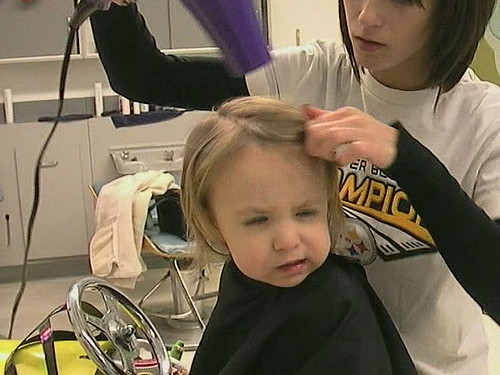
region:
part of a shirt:
[413, 218, 421, 233]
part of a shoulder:
[325, 318, 337, 320]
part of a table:
[138, 251, 145, 269]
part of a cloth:
[329, 335, 345, 342]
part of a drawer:
[73, 198, 81, 211]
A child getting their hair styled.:
[78, 3, 488, 373]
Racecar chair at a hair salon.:
[5, 272, 197, 372]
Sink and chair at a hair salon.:
[87, 138, 188, 274]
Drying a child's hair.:
[162, 4, 344, 294]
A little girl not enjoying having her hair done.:
[154, 14, 387, 294]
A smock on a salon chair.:
[88, 162, 197, 283]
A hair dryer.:
[41, 0, 268, 130]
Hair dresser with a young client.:
[143, 1, 454, 295]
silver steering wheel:
[64, 273, 171, 373]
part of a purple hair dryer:
[182, 0, 272, 76]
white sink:
[110, 142, 182, 173]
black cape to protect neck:
[187, 259, 419, 373]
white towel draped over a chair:
[90, 169, 178, 288]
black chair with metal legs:
[88, 177, 217, 327]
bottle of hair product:
[3, 87, 13, 124]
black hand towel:
[99, 108, 195, 128]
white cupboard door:
[14, 144, 86, 259]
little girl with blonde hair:
[179, 95, 420, 374]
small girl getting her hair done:
[177, 85, 347, 295]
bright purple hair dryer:
[55, 0, 277, 82]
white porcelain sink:
[106, 141, 190, 174]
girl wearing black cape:
[180, 91, 420, 373]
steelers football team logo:
[337, 218, 377, 263]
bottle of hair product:
[92, 77, 107, 118]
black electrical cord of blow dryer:
[10, 27, 80, 334]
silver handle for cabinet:
[35, 156, 63, 169]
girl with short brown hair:
[325, 0, 494, 106]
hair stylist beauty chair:
[84, 178, 221, 323]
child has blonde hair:
[160, 118, 345, 254]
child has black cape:
[221, 247, 391, 367]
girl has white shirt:
[276, 40, 491, 347]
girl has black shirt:
[67, 44, 260, 105]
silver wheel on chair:
[66, 232, 156, 374]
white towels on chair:
[82, 153, 169, 247]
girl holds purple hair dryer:
[187, 3, 277, 71]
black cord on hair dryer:
[2, 42, 74, 323]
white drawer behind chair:
[25, 142, 85, 262]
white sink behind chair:
[106, 144, 200, 184]